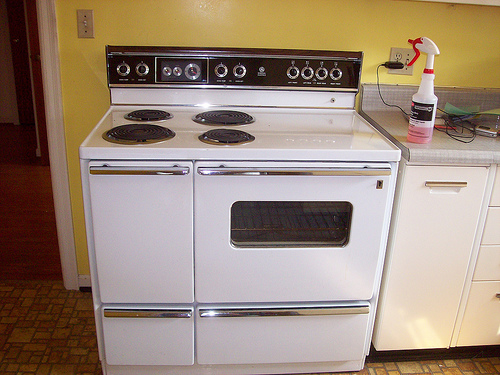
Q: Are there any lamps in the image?
A: No, there are no lamps.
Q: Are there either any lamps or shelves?
A: No, there are no lamps or shelves.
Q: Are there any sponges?
A: No, there are no sponges.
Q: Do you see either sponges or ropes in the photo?
A: No, there are no sponges or ropes.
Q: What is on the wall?
A: The switch is on the wall.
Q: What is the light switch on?
A: The light switch is on the wall.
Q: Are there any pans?
A: No, there are no pans.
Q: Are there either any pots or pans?
A: No, there are no pans or pots.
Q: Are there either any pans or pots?
A: No, there are no pans or pots.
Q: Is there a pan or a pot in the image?
A: No, there are no pans or pots.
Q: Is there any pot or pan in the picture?
A: No, there are no pans or pots.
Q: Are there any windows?
A: Yes, there is a window.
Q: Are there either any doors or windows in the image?
A: Yes, there is a window.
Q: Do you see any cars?
A: No, there are no cars.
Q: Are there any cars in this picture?
A: No, there are no cars.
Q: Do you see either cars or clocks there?
A: No, there are no cars or clocks.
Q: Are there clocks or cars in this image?
A: No, there are no cars or clocks.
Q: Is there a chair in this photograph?
A: No, there are no chairs.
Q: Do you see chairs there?
A: No, there are no chairs.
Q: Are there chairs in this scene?
A: No, there are no chairs.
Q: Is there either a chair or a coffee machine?
A: No, there are no chairs or coffee makers.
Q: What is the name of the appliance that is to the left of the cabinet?
A: The appliance is a stove.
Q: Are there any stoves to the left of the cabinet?
A: Yes, there is a stove to the left of the cabinet.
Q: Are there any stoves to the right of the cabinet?
A: No, the stove is to the left of the cabinet.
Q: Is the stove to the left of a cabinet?
A: Yes, the stove is to the left of a cabinet.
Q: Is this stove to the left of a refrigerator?
A: No, the stove is to the left of a cabinet.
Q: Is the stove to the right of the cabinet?
A: No, the stove is to the left of the cabinet.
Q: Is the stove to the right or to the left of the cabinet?
A: The stove is to the left of the cabinet.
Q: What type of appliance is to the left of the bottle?
A: The appliance is a stove.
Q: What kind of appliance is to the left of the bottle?
A: The appliance is a stove.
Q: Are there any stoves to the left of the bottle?
A: Yes, there is a stove to the left of the bottle.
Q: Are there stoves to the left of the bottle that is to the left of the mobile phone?
A: Yes, there is a stove to the left of the bottle.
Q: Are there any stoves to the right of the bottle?
A: No, the stove is to the left of the bottle.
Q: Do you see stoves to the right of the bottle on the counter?
A: No, the stove is to the left of the bottle.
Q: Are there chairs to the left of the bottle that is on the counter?
A: No, there is a stove to the left of the bottle.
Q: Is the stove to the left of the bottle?
A: Yes, the stove is to the left of the bottle.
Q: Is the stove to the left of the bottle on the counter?
A: Yes, the stove is to the left of the bottle.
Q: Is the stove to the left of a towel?
A: No, the stove is to the left of the bottle.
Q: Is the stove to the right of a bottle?
A: No, the stove is to the left of a bottle.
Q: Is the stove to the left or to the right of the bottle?
A: The stove is to the left of the bottle.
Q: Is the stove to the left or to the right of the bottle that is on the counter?
A: The stove is to the left of the bottle.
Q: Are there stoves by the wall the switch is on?
A: Yes, there is a stove by the wall.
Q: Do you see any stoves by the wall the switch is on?
A: Yes, there is a stove by the wall.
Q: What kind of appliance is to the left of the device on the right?
A: The appliance is a stove.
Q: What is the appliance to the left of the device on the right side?
A: The appliance is a stove.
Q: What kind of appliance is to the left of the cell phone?
A: The appliance is a stove.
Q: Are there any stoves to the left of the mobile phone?
A: Yes, there is a stove to the left of the mobile phone.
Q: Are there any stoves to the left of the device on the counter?
A: Yes, there is a stove to the left of the mobile phone.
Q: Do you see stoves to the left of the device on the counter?
A: Yes, there is a stove to the left of the mobile phone.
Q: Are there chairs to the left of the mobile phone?
A: No, there is a stove to the left of the mobile phone.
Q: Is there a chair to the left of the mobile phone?
A: No, there is a stove to the left of the mobile phone.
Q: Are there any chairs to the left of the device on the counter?
A: No, there is a stove to the left of the mobile phone.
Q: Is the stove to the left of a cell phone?
A: Yes, the stove is to the left of a cell phone.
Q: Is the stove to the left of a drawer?
A: No, the stove is to the left of a cell phone.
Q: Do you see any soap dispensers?
A: No, there are no soap dispensers.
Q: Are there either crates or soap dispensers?
A: No, there are no soap dispensers or crates.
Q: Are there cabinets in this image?
A: Yes, there is a cabinet.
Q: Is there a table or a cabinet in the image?
A: Yes, there is a cabinet.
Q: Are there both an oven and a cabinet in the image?
A: Yes, there are both a cabinet and an oven.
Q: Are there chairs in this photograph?
A: No, there are no chairs.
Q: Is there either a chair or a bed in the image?
A: No, there are no chairs or beds.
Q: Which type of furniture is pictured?
A: The furniture is a cabinet.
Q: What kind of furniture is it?
A: The piece of furniture is a cabinet.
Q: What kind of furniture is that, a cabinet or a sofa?
A: This is a cabinet.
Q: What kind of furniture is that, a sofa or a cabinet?
A: This is a cabinet.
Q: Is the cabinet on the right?
A: Yes, the cabinet is on the right of the image.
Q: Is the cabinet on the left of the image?
A: No, the cabinet is on the right of the image.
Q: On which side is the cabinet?
A: The cabinet is on the right of the image.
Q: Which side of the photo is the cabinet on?
A: The cabinet is on the right of the image.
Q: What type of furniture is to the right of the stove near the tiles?
A: The piece of furniture is a cabinet.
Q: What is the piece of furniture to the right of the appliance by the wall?
A: The piece of furniture is a cabinet.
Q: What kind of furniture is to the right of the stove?
A: The piece of furniture is a cabinet.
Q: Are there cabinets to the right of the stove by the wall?
A: Yes, there is a cabinet to the right of the stove.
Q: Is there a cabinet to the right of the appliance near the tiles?
A: Yes, there is a cabinet to the right of the stove.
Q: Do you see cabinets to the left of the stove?
A: No, the cabinet is to the right of the stove.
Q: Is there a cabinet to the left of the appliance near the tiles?
A: No, the cabinet is to the right of the stove.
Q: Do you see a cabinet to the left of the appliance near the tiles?
A: No, the cabinet is to the right of the stove.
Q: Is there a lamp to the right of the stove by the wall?
A: No, there is a cabinet to the right of the stove.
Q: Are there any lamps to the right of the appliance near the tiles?
A: No, there is a cabinet to the right of the stove.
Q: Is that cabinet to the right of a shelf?
A: No, the cabinet is to the right of a stove.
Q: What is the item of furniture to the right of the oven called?
A: The piece of furniture is a cabinet.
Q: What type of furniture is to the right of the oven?
A: The piece of furniture is a cabinet.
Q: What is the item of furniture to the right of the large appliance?
A: The piece of furniture is a cabinet.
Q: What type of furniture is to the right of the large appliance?
A: The piece of furniture is a cabinet.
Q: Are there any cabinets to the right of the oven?
A: Yes, there is a cabinet to the right of the oven.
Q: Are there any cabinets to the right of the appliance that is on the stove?
A: Yes, there is a cabinet to the right of the oven.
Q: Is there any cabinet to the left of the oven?
A: No, the cabinet is to the right of the oven.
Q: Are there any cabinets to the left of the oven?
A: No, the cabinet is to the right of the oven.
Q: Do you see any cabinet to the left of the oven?
A: No, the cabinet is to the right of the oven.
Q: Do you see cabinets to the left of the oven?
A: No, the cabinet is to the right of the oven.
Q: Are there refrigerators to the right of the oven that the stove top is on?
A: No, there is a cabinet to the right of the oven.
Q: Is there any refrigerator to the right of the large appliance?
A: No, there is a cabinet to the right of the oven.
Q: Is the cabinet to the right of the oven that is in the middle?
A: Yes, the cabinet is to the right of the oven.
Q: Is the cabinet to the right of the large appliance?
A: Yes, the cabinet is to the right of the oven.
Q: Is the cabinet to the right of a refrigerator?
A: No, the cabinet is to the right of the oven.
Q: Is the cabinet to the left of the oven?
A: No, the cabinet is to the right of the oven.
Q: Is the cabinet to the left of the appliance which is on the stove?
A: No, the cabinet is to the right of the oven.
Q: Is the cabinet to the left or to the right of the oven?
A: The cabinet is to the right of the oven.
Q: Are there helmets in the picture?
A: No, there are no helmets.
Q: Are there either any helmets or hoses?
A: No, there are no helmets or hoses.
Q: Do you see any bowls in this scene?
A: No, there are no bowls.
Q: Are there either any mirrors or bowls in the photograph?
A: No, there are no bowls or mirrors.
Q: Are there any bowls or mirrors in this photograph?
A: No, there are no bowls or mirrors.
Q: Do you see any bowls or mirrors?
A: No, there are no bowls or mirrors.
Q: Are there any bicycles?
A: No, there are no bicycles.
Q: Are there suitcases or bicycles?
A: No, there are no bicycles or suitcases.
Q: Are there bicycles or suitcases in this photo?
A: No, there are no bicycles or suitcases.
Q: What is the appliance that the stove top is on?
A: The appliance is a stove.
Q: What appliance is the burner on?
A: The stove top is on the stove.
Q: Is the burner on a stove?
A: Yes, the burner is on a stove.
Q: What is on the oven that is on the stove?
A: The stove top is on the oven.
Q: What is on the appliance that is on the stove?
A: The stove top is on the oven.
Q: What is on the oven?
A: The stove top is on the oven.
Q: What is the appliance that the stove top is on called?
A: The appliance is an oven.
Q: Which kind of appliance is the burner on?
A: The stove top is on the oven.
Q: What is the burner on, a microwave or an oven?
A: The burner is on an oven.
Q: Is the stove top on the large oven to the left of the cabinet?
A: Yes, the stove top is on the oven.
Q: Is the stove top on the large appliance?
A: Yes, the stove top is on the oven.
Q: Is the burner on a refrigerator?
A: No, the burner is on the oven.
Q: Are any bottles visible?
A: Yes, there is a bottle.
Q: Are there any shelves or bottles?
A: Yes, there is a bottle.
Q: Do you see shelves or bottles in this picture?
A: Yes, there is a bottle.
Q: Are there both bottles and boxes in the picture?
A: No, there is a bottle but no boxes.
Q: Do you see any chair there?
A: No, there are no chairs.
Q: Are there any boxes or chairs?
A: No, there are no chairs or boxes.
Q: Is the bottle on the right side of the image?
A: Yes, the bottle is on the right of the image.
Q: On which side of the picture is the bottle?
A: The bottle is on the right of the image.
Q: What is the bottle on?
A: The bottle is on the counter.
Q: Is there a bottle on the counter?
A: Yes, there is a bottle on the counter.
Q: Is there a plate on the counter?
A: No, there is a bottle on the counter.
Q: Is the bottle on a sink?
A: No, the bottle is on the counter.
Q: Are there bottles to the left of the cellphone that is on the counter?
A: Yes, there is a bottle to the left of the cellphone.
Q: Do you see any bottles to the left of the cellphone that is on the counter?
A: Yes, there is a bottle to the left of the cellphone.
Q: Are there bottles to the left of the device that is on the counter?
A: Yes, there is a bottle to the left of the cellphone.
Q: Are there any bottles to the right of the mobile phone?
A: No, the bottle is to the left of the mobile phone.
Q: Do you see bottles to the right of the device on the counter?
A: No, the bottle is to the left of the mobile phone.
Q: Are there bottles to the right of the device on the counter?
A: No, the bottle is to the left of the mobile phone.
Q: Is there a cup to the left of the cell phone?
A: No, there is a bottle to the left of the cell phone.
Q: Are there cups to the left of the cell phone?
A: No, there is a bottle to the left of the cell phone.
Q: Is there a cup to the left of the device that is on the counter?
A: No, there is a bottle to the left of the cell phone.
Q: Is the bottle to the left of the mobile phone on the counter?
A: Yes, the bottle is to the left of the mobile phone.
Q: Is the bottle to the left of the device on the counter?
A: Yes, the bottle is to the left of the mobile phone.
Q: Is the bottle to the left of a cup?
A: No, the bottle is to the left of the mobile phone.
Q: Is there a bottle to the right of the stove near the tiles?
A: Yes, there is a bottle to the right of the stove.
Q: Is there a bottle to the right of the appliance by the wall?
A: Yes, there is a bottle to the right of the stove.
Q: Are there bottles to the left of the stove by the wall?
A: No, the bottle is to the right of the stove.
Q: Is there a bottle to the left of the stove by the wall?
A: No, the bottle is to the right of the stove.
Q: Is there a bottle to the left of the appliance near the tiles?
A: No, the bottle is to the right of the stove.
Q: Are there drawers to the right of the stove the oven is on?
A: No, there is a bottle to the right of the stove.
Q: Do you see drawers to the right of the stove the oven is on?
A: No, there is a bottle to the right of the stove.